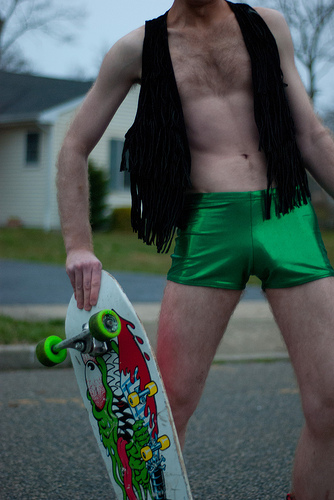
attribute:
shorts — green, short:
[161, 178, 333, 293]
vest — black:
[113, 3, 323, 250]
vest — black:
[153, 144, 173, 181]